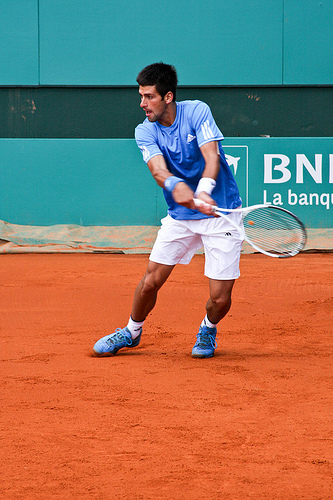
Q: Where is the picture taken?
A: Tennis court.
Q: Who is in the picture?
A: A man.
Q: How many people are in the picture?
A: One.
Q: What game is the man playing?
A: Tennis.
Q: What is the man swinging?
A: A racket.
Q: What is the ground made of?
A: Dirt.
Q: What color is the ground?
A: Red.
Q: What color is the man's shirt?
A: Blue.